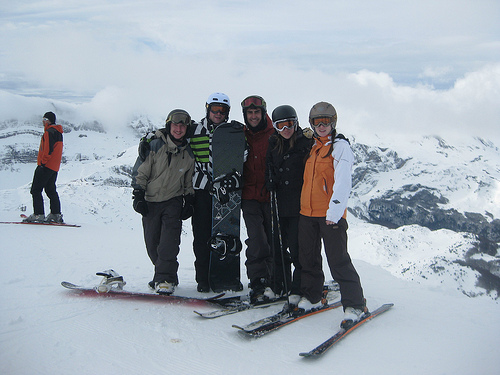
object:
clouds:
[53, 52, 124, 70]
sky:
[82, 124, 128, 148]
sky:
[57, 71, 97, 93]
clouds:
[425, 70, 498, 108]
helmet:
[204, 90, 231, 115]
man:
[190, 94, 244, 294]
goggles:
[206, 103, 231, 116]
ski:
[230, 300, 342, 335]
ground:
[436, 327, 499, 374]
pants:
[142, 196, 182, 286]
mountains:
[472, 215, 499, 283]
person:
[238, 96, 276, 302]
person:
[295, 102, 369, 326]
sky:
[462, 2, 499, 37]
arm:
[323, 138, 355, 222]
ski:
[299, 301, 394, 361]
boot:
[294, 296, 326, 316]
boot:
[338, 305, 368, 329]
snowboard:
[62, 266, 242, 304]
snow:
[0, 331, 55, 373]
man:
[130, 108, 195, 295]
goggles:
[163, 109, 193, 125]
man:
[28, 110, 63, 220]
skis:
[4, 214, 83, 228]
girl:
[261, 106, 312, 304]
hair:
[273, 111, 300, 124]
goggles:
[270, 116, 295, 131]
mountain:
[383, 176, 443, 236]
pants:
[298, 216, 366, 307]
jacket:
[302, 140, 361, 225]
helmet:
[301, 93, 341, 124]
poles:
[263, 183, 295, 307]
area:
[282, 30, 434, 93]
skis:
[228, 313, 394, 358]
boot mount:
[81, 265, 132, 292]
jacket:
[28, 121, 76, 179]